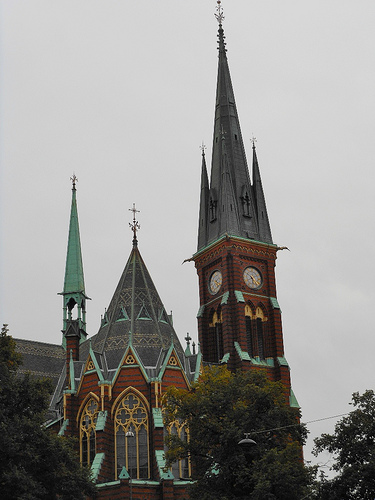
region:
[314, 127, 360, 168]
part of the cloud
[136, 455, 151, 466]
part of a window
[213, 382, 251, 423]
top of a tree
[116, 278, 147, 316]
top roof of a tower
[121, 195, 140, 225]
part of a cross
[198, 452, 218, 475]
part of a branch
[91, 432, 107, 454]
edge of the building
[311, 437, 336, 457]
part of some leaves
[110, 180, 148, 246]
A cross on the top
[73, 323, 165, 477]
The building is teal and brown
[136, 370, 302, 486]
Trees in front of the building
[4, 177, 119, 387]
The point of the building is teal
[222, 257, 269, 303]
A clock on the building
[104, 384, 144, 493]
The windows are gold color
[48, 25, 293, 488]
A castle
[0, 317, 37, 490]
More trees in front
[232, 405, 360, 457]
A power line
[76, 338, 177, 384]
The building is pointy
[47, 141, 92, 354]
green and slender spire on top of building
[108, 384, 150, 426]
four-leaf pattern within circles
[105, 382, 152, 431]
yellow circles underneath an arch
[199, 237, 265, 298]
clocks on two sides of a building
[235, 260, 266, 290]
gold hands and ornamentation on a grey face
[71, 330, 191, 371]
a row of triangles topping a building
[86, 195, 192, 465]
a religious cross on top of a circular tower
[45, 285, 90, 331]
four columns on corners of open space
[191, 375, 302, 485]
dark lamp bulb in front of a tree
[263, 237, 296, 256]
perpendicular point extending from corner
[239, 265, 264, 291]
clock with gold hands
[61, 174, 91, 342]
narrow turquoise church steeple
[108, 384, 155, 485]
ornamental gold trim on arched window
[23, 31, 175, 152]
light grey overcast sky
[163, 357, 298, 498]
green leaves on tree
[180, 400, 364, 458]
utility wire with light hanging from it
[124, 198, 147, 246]
cross on top of steeple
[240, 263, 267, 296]
clock telling time is 5:20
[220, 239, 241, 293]
brick on building with black mortar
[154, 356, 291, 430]
yellowing leaves on top of tree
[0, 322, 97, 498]
First tree on the left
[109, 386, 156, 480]
Middle arched window in the middle tower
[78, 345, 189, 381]
Three triangles above the arched windows in the middle tower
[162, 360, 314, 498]
Lightest green tree in front of the tallest tower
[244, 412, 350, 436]
Wire between the last two trees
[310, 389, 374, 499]
Last tree on the right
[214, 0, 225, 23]
Weather vane on top of the tallest structure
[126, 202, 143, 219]
Cross on top of the middle structure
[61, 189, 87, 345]
Aqua blue tower on the left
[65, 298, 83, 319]
Open portion in the middle of the left tower